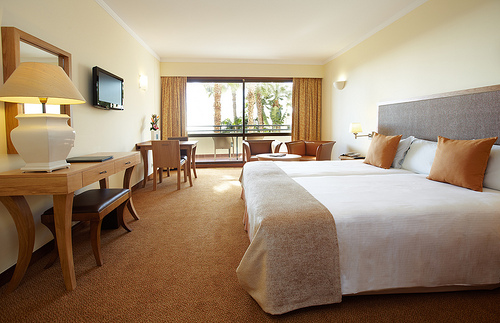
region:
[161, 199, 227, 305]
part of the brown carpet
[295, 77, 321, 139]
a brown curtain on the window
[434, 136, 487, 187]
a pillow on the bed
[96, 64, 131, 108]
a flat screen television on wall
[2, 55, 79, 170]
a white lamp and shade on desk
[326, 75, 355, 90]
a light on the wall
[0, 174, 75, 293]
legs on the wooden table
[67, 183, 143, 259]
a leather black bench on carpet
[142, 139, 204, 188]
a table with several chairs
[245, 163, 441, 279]
part of the brown and white blanket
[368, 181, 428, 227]
the blanket is white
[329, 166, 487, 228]
the bed is made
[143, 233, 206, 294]
the carpet is clean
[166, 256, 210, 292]
the carpet is brown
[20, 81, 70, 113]
the light is on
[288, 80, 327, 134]
the curtains are open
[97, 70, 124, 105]
the tv is off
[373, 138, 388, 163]
the pillow is standing upward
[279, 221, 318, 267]
the blanket is folded at the end of the bed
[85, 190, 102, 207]
the cusion is black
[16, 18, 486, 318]
a nice hotel room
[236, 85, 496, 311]
a huge king sized bed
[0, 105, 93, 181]
the base of the lamp is white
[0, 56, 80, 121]
the shade of the lamp is beige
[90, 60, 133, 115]
a flat screen tv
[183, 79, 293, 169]
a patio outside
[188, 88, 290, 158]
a double sliding glass door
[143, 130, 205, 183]
a table & chairs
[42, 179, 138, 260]
the stool is covered in black leather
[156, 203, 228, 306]
the carpet is light brown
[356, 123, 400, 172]
the pillow is orange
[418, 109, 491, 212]
the pillow is orange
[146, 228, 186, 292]
the floor is carpeted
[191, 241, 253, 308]
the floor is carpeted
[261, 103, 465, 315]
the bed is made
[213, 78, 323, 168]
the chair is empty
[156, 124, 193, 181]
the chair is empty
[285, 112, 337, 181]
the chair is empty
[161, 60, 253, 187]
the curtain is drawn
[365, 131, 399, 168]
brown rectangular pillow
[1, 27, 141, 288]
wooden desk with drawers, lamp and bench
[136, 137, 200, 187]
wooden table with two wooden chairs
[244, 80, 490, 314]
large made hotel bed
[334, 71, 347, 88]
wall mounted light fixture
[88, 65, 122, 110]
wall mounted flat screen tv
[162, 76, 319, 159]
large picture windows with gold drapes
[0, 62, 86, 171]
white table lamp with cream colored shade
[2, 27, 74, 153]
wood framed wall mounted mirror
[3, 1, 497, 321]
spacious oversize hotel room decorated in white, browns, and gold